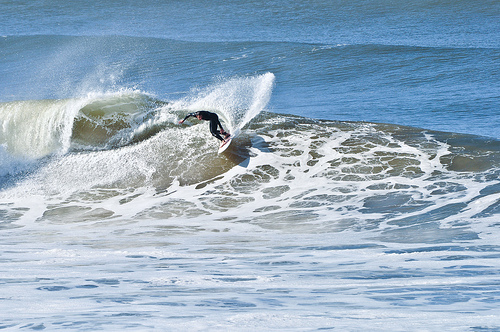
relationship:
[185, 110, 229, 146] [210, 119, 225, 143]
man wearing pants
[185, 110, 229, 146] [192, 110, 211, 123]
man wearing shirt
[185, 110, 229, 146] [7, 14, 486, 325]
man surfing in ocean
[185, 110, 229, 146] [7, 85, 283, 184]
man on waves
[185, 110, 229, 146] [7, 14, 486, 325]
man on ocean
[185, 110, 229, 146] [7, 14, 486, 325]
man in ocean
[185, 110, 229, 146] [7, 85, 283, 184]
man riding on waves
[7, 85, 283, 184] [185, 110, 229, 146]
waves under man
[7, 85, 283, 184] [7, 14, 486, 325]
waves in ocean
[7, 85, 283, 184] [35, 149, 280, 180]
waves have caps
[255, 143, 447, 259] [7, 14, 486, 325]
foam on ocean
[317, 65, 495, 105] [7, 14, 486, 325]
ripple in ocean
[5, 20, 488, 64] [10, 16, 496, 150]
wave in background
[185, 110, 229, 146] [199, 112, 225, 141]
man in suit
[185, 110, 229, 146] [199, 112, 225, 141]
man wearing suit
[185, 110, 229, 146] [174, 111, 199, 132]
man has hand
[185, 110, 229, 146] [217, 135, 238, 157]
man on surfboard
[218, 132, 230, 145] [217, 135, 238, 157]
feet on surfboard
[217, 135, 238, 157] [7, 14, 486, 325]
surfboard on ocean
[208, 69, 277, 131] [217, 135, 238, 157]
water spray from surfboard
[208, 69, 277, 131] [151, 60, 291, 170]
water spray breaking surface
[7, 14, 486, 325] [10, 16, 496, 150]
ocean in background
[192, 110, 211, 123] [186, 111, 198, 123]
shirt has sleeves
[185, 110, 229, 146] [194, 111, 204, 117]
man has hair